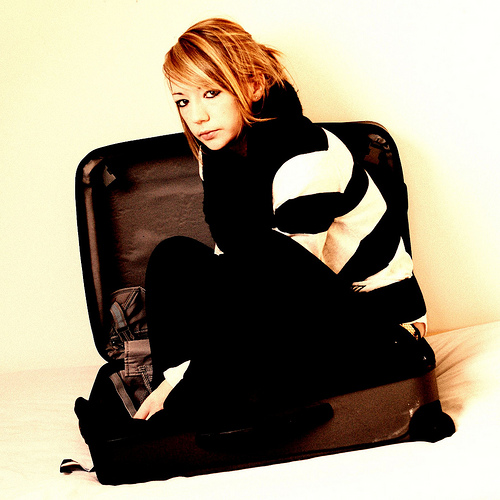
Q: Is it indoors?
A: Yes, it is indoors.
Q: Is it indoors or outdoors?
A: It is indoors.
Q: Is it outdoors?
A: No, it is indoors.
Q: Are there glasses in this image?
A: No, there are no glasses.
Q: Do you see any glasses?
A: No, there are no glasses.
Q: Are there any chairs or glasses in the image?
A: No, there are no glasses or chairs.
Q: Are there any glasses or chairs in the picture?
A: No, there are no glasses or chairs.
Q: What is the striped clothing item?
A: The clothing item is a sweater.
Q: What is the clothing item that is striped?
A: The clothing item is a sweater.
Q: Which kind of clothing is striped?
A: The clothing is a sweater.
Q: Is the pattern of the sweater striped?
A: Yes, the sweater is striped.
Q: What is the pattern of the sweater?
A: The sweater is striped.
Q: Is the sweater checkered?
A: No, the sweater is striped.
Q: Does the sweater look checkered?
A: No, the sweater is striped.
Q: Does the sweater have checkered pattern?
A: No, the sweater is striped.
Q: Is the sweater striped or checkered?
A: The sweater is striped.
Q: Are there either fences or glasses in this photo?
A: No, there are no glasses or fences.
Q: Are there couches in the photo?
A: No, there are no couches.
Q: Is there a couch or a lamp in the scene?
A: No, there are no couches or lamps.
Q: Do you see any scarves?
A: Yes, there is a scarf.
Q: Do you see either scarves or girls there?
A: Yes, there is a scarf.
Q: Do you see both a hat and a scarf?
A: No, there is a scarf but no hats.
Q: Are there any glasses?
A: No, there are no glasses.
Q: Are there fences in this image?
A: No, there are no fences.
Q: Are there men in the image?
A: No, there are no men.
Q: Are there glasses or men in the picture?
A: No, there are no men or glasses.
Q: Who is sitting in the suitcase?
A: The girl is sitting in the suitcase.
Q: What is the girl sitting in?
A: The girl is sitting in the suitcase.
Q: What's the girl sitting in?
A: The girl is sitting in the suitcase.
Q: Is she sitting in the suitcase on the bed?
A: Yes, the girl is sitting in the suitcase.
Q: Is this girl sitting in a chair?
A: No, the girl is sitting in the suitcase.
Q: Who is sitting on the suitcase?
A: The girl is sitting on the suitcase.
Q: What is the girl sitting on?
A: The girl is sitting on the suitcase.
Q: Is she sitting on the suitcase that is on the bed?
A: Yes, the girl is sitting on the suitcase.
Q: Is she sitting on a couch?
A: No, the girl is sitting on the suitcase.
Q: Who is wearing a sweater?
A: The girl is wearing a sweater.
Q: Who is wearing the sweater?
A: The girl is wearing a sweater.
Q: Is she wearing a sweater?
A: Yes, the girl is wearing a sweater.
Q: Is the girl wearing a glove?
A: No, the girl is wearing a sweater.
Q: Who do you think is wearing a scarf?
A: The girl is wearing a scarf.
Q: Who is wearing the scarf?
A: The girl is wearing a scarf.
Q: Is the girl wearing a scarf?
A: Yes, the girl is wearing a scarf.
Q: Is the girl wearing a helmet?
A: No, the girl is wearing a scarf.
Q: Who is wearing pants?
A: The girl is wearing pants.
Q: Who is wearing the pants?
A: The girl is wearing pants.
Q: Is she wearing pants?
A: Yes, the girl is wearing pants.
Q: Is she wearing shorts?
A: No, the girl is wearing pants.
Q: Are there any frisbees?
A: No, there are no frisbees.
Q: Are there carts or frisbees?
A: No, there are no frisbees or carts.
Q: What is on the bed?
A: The suitcase is on the bed.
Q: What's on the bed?
A: The suitcase is on the bed.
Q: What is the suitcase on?
A: The suitcase is on the bed.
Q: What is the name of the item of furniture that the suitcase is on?
A: The piece of furniture is a bed.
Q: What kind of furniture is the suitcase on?
A: The suitcase is on the bed.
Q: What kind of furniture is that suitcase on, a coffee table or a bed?
A: The suitcase is on a bed.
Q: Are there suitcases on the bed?
A: Yes, there is a suitcase on the bed.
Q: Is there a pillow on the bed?
A: No, there is a suitcase on the bed.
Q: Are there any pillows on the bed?
A: No, there is a suitcase on the bed.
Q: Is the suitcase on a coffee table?
A: No, the suitcase is on a bed.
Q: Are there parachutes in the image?
A: No, there are no parachutes.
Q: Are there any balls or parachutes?
A: No, there are no parachutes or balls.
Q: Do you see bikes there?
A: No, there are no bikes.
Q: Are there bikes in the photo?
A: No, there are no bikes.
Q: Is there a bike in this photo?
A: No, there are no bikes.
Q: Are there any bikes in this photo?
A: No, there are no bikes.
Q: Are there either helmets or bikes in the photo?
A: No, there are no bikes or helmets.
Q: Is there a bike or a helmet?
A: No, there are no bikes or helmets.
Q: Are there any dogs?
A: No, there are no dogs.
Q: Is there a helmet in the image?
A: No, there are no helmets.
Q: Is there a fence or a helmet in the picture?
A: No, there are no helmets or fences.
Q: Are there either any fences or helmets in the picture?
A: No, there are no helmets or fences.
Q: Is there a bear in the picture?
A: No, there are no bears.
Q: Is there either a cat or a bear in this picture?
A: No, there are no bears or cats.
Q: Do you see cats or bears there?
A: No, there are no bears or cats.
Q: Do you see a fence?
A: No, there are no fences.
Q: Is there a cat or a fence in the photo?
A: No, there are no fences or cats.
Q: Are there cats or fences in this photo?
A: No, there are no fences or cats.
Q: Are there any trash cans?
A: No, there are no trash cans.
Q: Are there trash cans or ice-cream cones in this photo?
A: No, there are no trash cans or ice-cream cones.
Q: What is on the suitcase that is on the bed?
A: The lid is on the suitcase.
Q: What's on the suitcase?
A: The lid is on the suitcase.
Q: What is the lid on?
A: The lid is on the suitcase.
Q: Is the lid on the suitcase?
A: Yes, the lid is on the suitcase.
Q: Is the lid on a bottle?
A: No, the lid is on the suitcase.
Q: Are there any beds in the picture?
A: Yes, there is a bed.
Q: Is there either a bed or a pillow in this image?
A: Yes, there is a bed.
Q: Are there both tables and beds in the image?
A: No, there is a bed but no tables.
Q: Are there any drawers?
A: No, there are no drawers.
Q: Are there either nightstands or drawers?
A: No, there are no drawers or nightstands.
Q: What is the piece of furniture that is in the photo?
A: The piece of furniture is a bed.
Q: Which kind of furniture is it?
A: The piece of furniture is a bed.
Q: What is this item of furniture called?
A: This is a bed.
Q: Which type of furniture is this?
A: This is a bed.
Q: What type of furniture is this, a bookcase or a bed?
A: This is a bed.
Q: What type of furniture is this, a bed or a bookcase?
A: This is a bed.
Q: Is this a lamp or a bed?
A: This is a bed.